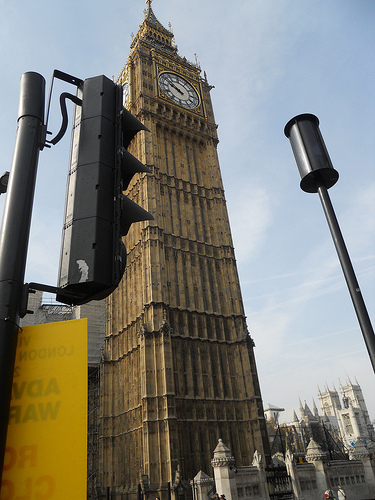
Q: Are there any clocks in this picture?
A: Yes, there is a clock.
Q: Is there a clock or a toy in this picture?
A: Yes, there is a clock.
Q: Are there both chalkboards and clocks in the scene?
A: No, there is a clock but no chalkboards.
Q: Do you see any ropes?
A: No, there are no ropes.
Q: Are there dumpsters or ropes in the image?
A: No, there are no ropes or dumpsters.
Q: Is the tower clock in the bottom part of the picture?
A: No, the clock is in the top of the image.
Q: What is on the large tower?
A: The clock is on the tower.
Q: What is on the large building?
A: The clock is on the tower.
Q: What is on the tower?
A: The clock is on the tower.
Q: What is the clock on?
A: The clock is on the tower.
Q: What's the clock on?
A: The clock is on the tower.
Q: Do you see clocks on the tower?
A: Yes, there is a clock on the tower.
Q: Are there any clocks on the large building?
A: Yes, there is a clock on the tower.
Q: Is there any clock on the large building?
A: Yes, there is a clock on the tower.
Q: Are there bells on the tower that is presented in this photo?
A: No, there is a clock on the tower.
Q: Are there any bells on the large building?
A: No, there is a clock on the tower.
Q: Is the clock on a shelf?
A: No, the clock is on a tower.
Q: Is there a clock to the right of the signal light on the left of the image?
A: Yes, there is a clock to the right of the traffic light.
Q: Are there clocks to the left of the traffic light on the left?
A: No, the clock is to the right of the traffic light.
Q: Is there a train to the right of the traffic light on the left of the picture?
A: No, there is a clock to the right of the traffic light.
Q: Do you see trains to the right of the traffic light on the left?
A: No, there is a clock to the right of the traffic light.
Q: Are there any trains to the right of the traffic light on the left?
A: No, there is a clock to the right of the traffic light.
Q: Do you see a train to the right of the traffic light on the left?
A: No, there is a clock to the right of the traffic light.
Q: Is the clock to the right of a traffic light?
A: Yes, the clock is to the right of a traffic light.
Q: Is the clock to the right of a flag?
A: No, the clock is to the right of a traffic light.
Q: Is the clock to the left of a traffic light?
A: No, the clock is to the right of a traffic light.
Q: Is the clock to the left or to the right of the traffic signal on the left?
A: The clock is to the right of the traffic light.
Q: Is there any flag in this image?
A: No, there are no flags.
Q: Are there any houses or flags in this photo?
A: No, there are no flags or houses.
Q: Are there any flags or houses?
A: No, there are no flags or houses.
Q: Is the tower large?
A: Yes, the tower is large.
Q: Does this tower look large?
A: Yes, the tower is large.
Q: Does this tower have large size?
A: Yes, the tower is large.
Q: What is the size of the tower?
A: The tower is large.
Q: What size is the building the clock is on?
A: The tower is large.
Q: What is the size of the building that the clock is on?
A: The tower is large.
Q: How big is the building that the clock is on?
A: The tower is large.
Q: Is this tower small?
A: No, the tower is large.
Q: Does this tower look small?
A: No, the tower is large.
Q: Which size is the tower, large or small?
A: The tower is large.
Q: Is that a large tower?
A: Yes, that is a large tower.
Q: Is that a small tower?
A: No, that is a large tower.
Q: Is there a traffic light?
A: Yes, there is a traffic light.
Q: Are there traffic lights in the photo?
A: Yes, there is a traffic light.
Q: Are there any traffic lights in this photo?
A: Yes, there is a traffic light.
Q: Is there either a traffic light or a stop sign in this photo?
A: Yes, there is a traffic light.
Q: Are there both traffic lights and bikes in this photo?
A: No, there is a traffic light but no bikes.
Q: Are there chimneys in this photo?
A: No, there are no chimneys.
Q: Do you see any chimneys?
A: No, there are no chimneys.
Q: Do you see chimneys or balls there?
A: No, there are no chimneys or balls.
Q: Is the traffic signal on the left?
A: Yes, the traffic signal is on the left of the image.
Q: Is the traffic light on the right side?
A: No, the traffic light is on the left of the image.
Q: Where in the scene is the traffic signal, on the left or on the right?
A: The traffic signal is on the left of the image.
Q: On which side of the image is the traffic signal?
A: The traffic signal is on the left of the image.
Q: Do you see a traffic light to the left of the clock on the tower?
A: Yes, there is a traffic light to the left of the clock.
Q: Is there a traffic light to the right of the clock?
A: No, the traffic light is to the left of the clock.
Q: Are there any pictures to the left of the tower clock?
A: No, there is a traffic light to the left of the clock.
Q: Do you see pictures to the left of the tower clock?
A: No, there is a traffic light to the left of the clock.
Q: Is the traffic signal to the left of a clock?
A: Yes, the traffic signal is to the left of a clock.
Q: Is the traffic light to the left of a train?
A: No, the traffic light is to the left of a clock.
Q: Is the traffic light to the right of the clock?
A: No, the traffic light is to the left of the clock.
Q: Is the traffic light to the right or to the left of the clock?
A: The traffic light is to the left of the clock.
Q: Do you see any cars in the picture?
A: No, there are no cars.